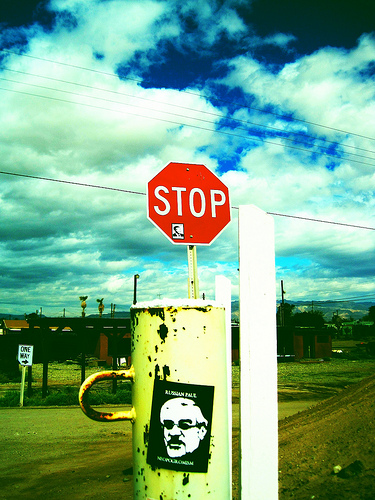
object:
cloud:
[232, 44, 373, 171]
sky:
[1, 3, 373, 303]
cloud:
[36, 0, 258, 66]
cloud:
[6, 46, 224, 173]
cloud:
[211, 140, 374, 258]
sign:
[149, 161, 231, 245]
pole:
[186, 247, 198, 298]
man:
[158, 397, 207, 457]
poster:
[145, 379, 215, 474]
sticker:
[170, 223, 184, 241]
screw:
[187, 164, 191, 172]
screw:
[188, 235, 194, 240]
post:
[127, 302, 235, 497]